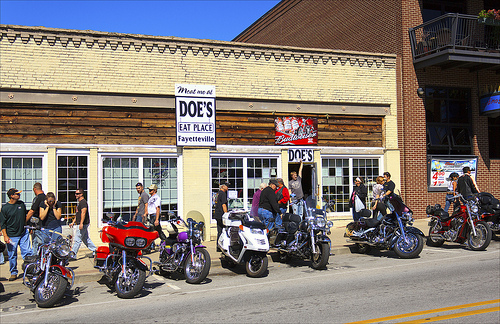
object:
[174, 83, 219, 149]
sign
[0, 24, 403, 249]
building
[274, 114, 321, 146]
sign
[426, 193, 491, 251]
motorcycle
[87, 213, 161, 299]
motorcycle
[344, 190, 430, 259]
motorcycle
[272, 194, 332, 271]
motorcycle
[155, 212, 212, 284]
motorcycle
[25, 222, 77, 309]
motorcycle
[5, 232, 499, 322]
road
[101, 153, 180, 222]
window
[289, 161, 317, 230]
doorway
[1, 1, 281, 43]
sky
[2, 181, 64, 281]
people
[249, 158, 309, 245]
people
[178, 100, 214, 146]
black lettering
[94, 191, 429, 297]
motorcycles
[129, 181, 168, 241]
people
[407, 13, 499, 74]
patio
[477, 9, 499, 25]
flower pot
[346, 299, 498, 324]
lines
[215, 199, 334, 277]
motobikes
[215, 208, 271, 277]
motorcycle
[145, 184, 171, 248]
man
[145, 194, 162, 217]
shirt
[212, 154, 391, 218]
windows